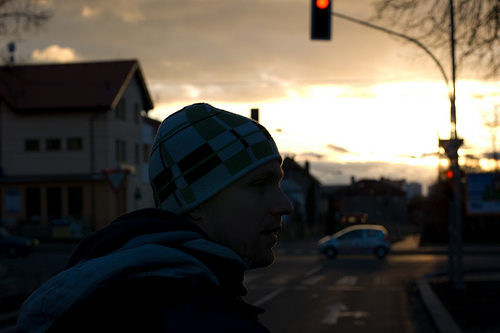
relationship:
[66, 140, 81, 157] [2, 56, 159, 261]
window on building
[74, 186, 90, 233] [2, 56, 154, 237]
window on building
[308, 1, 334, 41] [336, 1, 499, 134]
light on pole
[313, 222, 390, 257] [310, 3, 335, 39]
car under light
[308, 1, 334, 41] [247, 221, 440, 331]
light over street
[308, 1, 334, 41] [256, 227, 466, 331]
light at intersection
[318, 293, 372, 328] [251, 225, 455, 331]
arrow on street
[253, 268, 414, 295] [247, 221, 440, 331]
crosswalk on street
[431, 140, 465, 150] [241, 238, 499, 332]
sign for road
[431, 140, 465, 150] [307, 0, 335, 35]
sign above light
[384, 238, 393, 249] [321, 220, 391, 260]
tail light on car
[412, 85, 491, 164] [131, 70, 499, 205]
sun setting in background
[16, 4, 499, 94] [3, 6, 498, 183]
cloud cover in sky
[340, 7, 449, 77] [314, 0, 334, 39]
pole of traffic light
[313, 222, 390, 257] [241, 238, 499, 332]
car on road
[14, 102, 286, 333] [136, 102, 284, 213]
man in hat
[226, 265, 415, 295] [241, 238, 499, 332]
lines in road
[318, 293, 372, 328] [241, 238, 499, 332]
arrow in road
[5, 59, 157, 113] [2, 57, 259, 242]
roof on apartments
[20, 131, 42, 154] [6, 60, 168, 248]
window on building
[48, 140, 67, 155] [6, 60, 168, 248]
window on building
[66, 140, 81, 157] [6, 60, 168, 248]
window on building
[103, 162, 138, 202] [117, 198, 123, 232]
sign on pole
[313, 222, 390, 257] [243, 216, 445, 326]
car crossing street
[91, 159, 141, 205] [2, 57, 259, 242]
yield sign by apartments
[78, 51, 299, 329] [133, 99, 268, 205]
man wearing a hat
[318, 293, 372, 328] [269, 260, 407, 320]
arrow on road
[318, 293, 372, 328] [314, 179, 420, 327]
arrow on road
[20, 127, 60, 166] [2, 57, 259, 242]
window on apartments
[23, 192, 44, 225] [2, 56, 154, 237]
window on building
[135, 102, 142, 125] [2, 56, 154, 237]
window on building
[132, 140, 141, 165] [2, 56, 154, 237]
window on building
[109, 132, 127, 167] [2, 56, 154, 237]
window on building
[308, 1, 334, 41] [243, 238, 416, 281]
light at intersection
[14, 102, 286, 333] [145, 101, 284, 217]
man wearing beanie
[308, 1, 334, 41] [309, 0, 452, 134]
light on traffic signal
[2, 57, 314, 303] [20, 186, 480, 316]
apartments are in background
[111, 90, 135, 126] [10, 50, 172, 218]
window attached to building